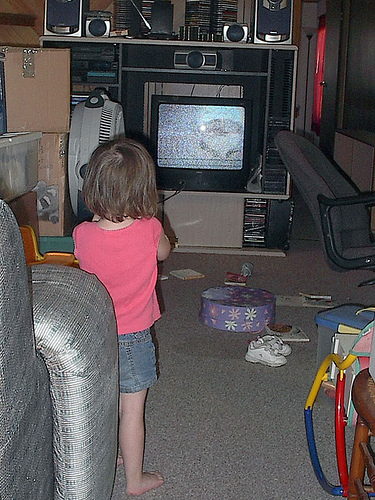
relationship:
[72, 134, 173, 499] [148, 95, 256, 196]
girl standing in front of television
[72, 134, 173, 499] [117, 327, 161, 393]
girl wearing shorts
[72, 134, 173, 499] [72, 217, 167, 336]
girl wearing top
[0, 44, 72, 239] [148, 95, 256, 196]
cardboard boxes to left of television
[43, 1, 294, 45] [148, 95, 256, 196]
speakers above television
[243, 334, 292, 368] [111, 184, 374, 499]
tennis shoes on carpet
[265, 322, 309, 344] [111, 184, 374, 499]
book on carpet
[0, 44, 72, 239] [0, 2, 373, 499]
cardboard boxes in livingroom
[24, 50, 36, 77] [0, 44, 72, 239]
tape on cardboard boxes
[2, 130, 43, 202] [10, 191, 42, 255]
box on table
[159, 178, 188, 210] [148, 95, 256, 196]
cables connect to television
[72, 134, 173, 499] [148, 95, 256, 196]
girl watching television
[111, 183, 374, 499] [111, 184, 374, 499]
floor has `carpet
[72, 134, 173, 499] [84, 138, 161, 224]
girl with hair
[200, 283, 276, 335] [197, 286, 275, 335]
box has flowers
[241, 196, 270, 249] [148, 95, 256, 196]
dvds below television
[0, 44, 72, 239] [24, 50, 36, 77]
cardboard boxes with tape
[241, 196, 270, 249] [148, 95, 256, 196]
dvds under television